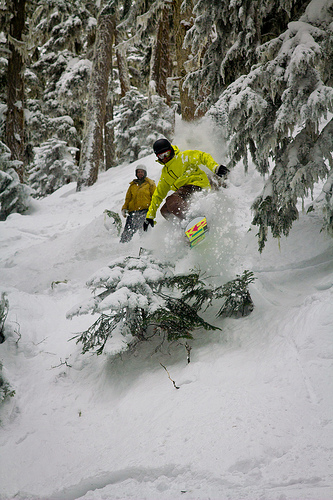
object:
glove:
[142, 218, 155, 232]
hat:
[134, 164, 147, 180]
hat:
[153, 138, 175, 163]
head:
[152, 138, 174, 163]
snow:
[150, 202, 239, 279]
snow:
[0, 411, 116, 497]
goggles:
[156, 150, 171, 160]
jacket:
[139, 144, 218, 220]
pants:
[160, 185, 200, 227]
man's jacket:
[121, 177, 156, 212]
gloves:
[216, 162, 225, 180]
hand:
[142, 217, 154, 232]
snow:
[258, 245, 306, 282]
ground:
[263, 235, 320, 310]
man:
[143, 138, 231, 235]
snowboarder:
[184, 212, 210, 248]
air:
[184, 216, 211, 250]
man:
[117, 150, 164, 232]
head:
[135, 162, 148, 180]